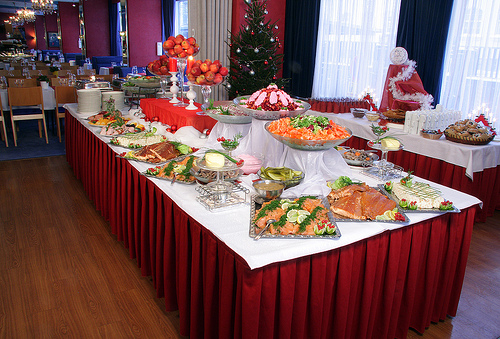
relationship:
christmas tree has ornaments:
[219, 0, 290, 99] [253, 48, 257, 52]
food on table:
[105, 50, 387, 256] [103, 41, 424, 306]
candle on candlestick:
[167, 56, 178, 71] [166, 70, 179, 102]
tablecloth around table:
[63, 98, 482, 339] [179, 177, 260, 273]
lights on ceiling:
[1, 6, 29, 26] [2, 0, 26, 6]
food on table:
[254, 195, 336, 234] [120, 73, 460, 308]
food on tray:
[325, 175, 407, 222] [248, 193, 266, 237]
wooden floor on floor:
[0, 152, 498, 336] [3, 137, 499, 337]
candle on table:
[167, 56, 178, 71] [59, 86, 475, 336]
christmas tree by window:
[219, 0, 290, 99] [312, 1, 402, 111]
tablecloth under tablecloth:
[63, 98, 482, 339] [63, 98, 482, 339]